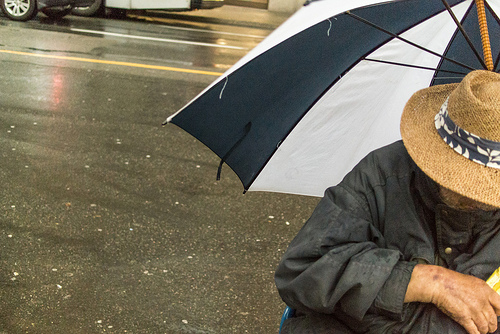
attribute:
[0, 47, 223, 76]
line — yellow